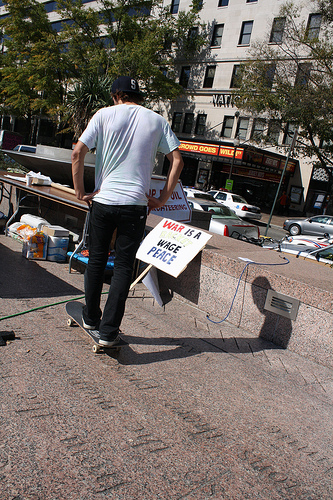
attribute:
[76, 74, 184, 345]
man — standing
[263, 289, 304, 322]
grate — silver, aluminum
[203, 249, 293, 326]
hose — blue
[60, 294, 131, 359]
skateboard — black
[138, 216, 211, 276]
sign — white, red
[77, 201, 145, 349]
jeans — blue, black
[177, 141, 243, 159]
sign — yellow, red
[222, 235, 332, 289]
wall edge — red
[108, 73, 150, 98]
baseball cap — blue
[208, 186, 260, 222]
police car — parked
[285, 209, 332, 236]
car — silver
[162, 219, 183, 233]
letters — red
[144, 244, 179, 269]
letters — blue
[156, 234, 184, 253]
letters — black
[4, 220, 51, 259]
packaging — white orange blue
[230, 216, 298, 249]
bicycle — black framed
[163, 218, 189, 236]
word — red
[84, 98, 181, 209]
t-shirt — white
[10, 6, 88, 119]
trees — green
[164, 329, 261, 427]
walk — cement